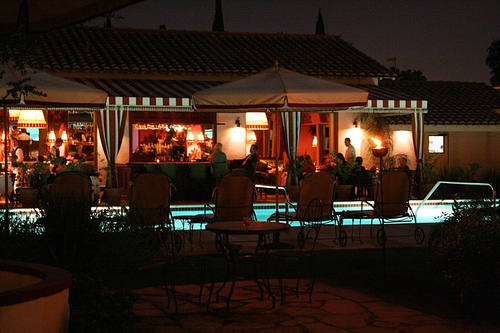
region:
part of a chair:
[225, 276, 237, 293]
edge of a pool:
[182, 220, 197, 223]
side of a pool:
[262, 218, 267, 230]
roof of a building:
[147, 44, 167, 83]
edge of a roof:
[138, 89, 145, 112]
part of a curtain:
[403, 139, 426, 151]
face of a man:
[341, 108, 361, 158]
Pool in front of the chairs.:
[13, 186, 499, 231]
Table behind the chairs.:
[196, 209, 288, 301]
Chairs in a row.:
[37, 162, 442, 237]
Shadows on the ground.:
[151, 285, 407, 331]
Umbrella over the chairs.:
[193, 55, 371, 127]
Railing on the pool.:
[417, 168, 488, 226]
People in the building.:
[8, 112, 94, 172]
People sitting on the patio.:
[210, 146, 385, 188]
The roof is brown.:
[23, 29, 498, 122]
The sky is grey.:
[345, 10, 499, 73]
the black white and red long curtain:
[97, 107, 127, 192]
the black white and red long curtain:
[279, 108, 301, 193]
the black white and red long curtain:
[409, 109, 426, 192]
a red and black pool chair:
[45, 170, 97, 237]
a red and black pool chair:
[126, 170, 174, 228]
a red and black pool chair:
[190, 175, 256, 235]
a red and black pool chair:
[267, 172, 342, 236]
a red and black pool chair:
[340, 166, 414, 229]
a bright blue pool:
[3, 198, 498, 231]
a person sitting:
[240, 143, 262, 170]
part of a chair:
[293, 245, 313, 297]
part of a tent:
[233, 72, 250, 113]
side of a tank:
[71, 313, 83, 325]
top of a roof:
[448, 98, 450, 102]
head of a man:
[213, 147, 222, 166]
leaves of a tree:
[459, 274, 475, 320]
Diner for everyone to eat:
[9, 108, 426, 181]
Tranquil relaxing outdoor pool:
[3, 201, 499, 221]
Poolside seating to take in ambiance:
[38, 147, 421, 254]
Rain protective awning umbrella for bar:
[178, 55, 377, 105]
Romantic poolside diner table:
[145, 190, 330, 320]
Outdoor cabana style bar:
[126, 131, 255, 176]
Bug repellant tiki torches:
[368, 133, 388, 255]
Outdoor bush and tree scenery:
[422, 190, 497, 318]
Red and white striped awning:
[100, 72, 198, 114]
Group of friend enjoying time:
[299, 135, 381, 177]